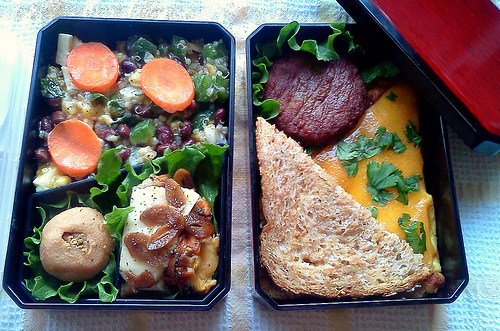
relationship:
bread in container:
[257, 119, 363, 287] [245, 23, 470, 311]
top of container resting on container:
[361, 3, 499, 99] [245, 23, 470, 311]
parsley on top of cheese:
[372, 164, 408, 198] [378, 103, 406, 135]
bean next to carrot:
[123, 61, 139, 75] [71, 41, 117, 91]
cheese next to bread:
[378, 103, 406, 135] [257, 119, 363, 287]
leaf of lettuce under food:
[101, 161, 135, 231] [35, 173, 219, 304]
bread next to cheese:
[257, 119, 363, 287] [378, 103, 406, 135]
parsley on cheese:
[372, 164, 408, 198] [378, 103, 406, 135]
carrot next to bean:
[71, 41, 117, 91] [123, 61, 139, 75]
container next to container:
[245, 23, 470, 311] [4, 9, 239, 310]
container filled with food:
[245, 23, 470, 311] [35, 173, 219, 304]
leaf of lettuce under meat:
[267, 25, 341, 57] [263, 52, 368, 141]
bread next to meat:
[257, 119, 363, 287] [263, 52, 368, 141]